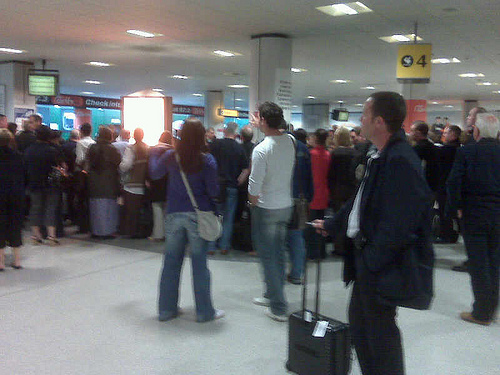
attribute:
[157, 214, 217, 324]
jeans — blue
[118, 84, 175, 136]
sign — brightly lit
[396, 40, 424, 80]
sign — yellow, black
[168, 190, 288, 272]
bag — white 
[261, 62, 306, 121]
sign — large, white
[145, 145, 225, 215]
blue shirt — blue 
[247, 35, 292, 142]
pillar — large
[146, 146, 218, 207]
shirt — blue 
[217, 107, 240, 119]
sign — lit up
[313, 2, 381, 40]
light — recessed 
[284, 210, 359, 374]
suitcase — black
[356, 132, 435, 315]
jacket — dark colored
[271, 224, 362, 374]
suitcase — pull along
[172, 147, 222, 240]
bag — white 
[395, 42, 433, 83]
sign — yellow 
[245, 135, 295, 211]
shirt — white 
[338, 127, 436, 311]
jacket — black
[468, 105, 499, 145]
head — balding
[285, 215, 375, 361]
suit case — black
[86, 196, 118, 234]
skirt — long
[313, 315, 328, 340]
tag — white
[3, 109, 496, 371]
crowd — large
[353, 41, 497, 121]
sign — 4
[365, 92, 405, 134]
brown hair — brown  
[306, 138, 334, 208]
sweater — red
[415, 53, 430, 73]
4 — number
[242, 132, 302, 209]
shirt — white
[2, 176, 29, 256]
pants — short 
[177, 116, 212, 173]
hair — brown  